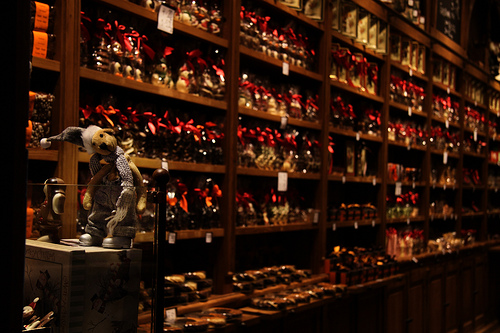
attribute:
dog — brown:
[38, 124, 146, 248]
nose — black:
[98, 140, 106, 147]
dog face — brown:
[83, 125, 121, 162]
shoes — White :
[57, 215, 142, 265]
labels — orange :
[30, 0, 53, 60]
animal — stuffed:
[34, 125, 155, 250]